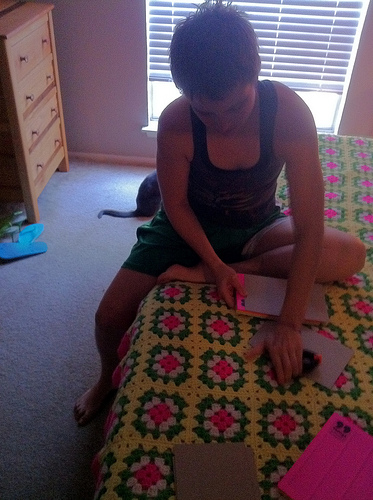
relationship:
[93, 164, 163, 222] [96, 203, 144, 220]
cat has tail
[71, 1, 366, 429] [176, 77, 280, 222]
boy wearing tank top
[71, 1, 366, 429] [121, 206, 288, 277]
boy wearing shorts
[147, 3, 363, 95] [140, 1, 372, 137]
blind on window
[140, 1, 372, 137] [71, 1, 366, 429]
window behind boy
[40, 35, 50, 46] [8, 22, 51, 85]
knob on drawer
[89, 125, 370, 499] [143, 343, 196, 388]
blanket has square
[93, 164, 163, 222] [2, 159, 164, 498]
cat on floor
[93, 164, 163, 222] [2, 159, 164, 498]
cat on ground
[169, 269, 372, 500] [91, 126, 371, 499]
stuff on bed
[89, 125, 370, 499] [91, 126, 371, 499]
quilt on bed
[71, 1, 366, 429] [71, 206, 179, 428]
boy has leg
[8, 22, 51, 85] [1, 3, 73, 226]
drawer on dresser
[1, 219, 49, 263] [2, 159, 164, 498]
flip flops on ground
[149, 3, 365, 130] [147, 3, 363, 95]
glare on blinds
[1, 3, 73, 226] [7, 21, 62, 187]
dresser has four drawers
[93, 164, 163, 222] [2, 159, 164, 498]
cat sitting on floor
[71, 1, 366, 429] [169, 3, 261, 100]
boy has short hair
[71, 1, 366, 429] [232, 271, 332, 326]
boy holding tablet of paper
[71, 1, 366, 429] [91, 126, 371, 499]
boy sitting on bed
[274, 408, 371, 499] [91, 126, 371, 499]
pink note on bed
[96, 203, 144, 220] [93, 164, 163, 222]
tail of gray cat